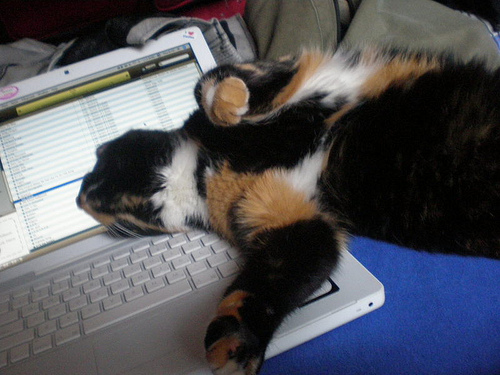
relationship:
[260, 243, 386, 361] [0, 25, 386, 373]
edge of laptop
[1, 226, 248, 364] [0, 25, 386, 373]
key pad of laptop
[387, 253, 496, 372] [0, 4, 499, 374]
top of table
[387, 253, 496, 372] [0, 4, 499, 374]
part of table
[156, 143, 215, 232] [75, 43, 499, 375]
white on cat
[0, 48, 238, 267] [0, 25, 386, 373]
screen of laptop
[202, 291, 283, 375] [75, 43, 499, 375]
paws of cat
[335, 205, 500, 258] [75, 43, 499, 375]
back of cat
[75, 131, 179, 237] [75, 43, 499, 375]
face of cat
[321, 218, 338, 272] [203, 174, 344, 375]
edge of leg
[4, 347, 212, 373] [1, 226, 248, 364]
edge of keyboard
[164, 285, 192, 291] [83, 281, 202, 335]
part of button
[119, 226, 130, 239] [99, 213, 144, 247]
part of whisker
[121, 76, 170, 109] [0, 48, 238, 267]
part of screen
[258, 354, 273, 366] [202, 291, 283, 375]
edge of paw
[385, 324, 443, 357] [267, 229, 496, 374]
part of surface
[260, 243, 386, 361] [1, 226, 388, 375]
edge of keyboard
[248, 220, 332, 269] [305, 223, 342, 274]
part of knee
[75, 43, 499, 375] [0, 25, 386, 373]
cat on computer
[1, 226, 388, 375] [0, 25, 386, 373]
keyboard on computer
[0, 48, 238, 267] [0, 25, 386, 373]
screen on laptop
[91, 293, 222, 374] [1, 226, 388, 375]
trackpad on keyboard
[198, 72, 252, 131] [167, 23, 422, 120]
paw in air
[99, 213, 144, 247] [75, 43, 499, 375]
whiskers on cat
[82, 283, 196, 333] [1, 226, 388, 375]
spacebar on keyboard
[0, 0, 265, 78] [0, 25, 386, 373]
clothes behind computer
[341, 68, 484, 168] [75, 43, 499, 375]
belly on cat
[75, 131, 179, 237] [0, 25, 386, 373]
head on computer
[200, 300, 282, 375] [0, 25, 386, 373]
paws on computer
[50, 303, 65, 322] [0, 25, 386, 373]
key on computer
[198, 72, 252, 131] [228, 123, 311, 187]
paws on chest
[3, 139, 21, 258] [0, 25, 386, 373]
lens on computer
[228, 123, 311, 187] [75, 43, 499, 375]
chest on cat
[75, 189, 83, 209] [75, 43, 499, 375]
nose on cat